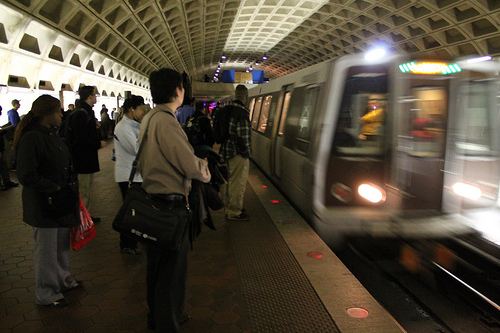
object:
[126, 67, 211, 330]
person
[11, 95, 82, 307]
woman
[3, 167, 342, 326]
platform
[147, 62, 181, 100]
hair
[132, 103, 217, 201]
shirt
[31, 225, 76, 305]
pants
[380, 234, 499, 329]
tracks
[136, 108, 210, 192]
coat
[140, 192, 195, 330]
pants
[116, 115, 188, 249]
bag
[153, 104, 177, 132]
shoulder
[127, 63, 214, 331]
man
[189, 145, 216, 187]
bag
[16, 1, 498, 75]
ceiling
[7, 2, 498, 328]
train station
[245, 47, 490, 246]
train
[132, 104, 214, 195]
sweater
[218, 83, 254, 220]
man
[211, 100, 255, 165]
shirt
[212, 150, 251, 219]
pants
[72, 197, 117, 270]
plastic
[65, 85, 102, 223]
people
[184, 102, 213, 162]
people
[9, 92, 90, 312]
person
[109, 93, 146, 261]
person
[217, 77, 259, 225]
person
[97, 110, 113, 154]
person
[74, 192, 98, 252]
red bag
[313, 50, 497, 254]
lights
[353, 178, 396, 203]
train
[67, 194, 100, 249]
bag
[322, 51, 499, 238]
front end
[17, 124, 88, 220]
coat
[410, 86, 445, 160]
window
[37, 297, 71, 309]
shoe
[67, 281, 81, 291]
shoe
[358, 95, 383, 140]
passenger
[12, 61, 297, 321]
people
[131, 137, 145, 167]
strap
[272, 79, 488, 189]
train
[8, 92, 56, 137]
hair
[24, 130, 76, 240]
jacket